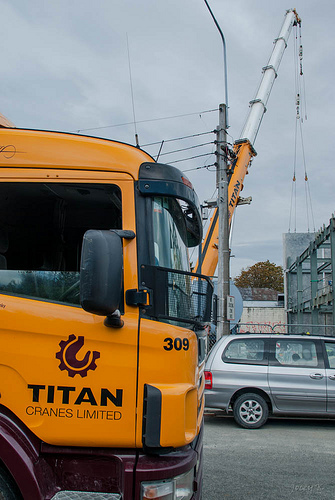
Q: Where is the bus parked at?
A: On the side of the street.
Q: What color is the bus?
A: Yellow.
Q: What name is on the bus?
A: Titan cranes limited.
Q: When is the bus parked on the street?
A: Now.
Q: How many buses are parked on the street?
A: One.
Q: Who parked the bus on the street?
A: A person.